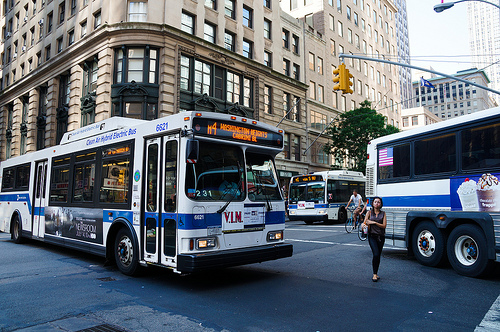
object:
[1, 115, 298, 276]
bus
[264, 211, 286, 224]
blue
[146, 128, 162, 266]
doors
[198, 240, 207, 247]
headlights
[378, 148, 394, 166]
flag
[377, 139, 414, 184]
window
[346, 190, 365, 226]
man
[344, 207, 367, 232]
bicycle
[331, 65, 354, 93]
stoplight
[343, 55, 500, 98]
pole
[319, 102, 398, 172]
tree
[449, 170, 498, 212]
advertisement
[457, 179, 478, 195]
icecream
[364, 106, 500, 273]
bus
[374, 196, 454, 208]
blue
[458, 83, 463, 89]
window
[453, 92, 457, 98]
window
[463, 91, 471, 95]
window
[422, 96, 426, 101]
window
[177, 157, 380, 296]
intersection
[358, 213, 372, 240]
bike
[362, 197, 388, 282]
lady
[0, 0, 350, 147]
buildings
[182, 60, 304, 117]
row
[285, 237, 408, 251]
lines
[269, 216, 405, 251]
crosswalk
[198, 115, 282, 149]
sign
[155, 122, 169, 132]
6621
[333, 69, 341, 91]
light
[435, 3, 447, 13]
light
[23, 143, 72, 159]
edge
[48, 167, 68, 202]
window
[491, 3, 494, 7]
metal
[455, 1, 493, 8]
pole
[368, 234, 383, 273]
jeans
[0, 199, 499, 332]
road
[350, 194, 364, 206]
shirt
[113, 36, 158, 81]
window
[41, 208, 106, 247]
advertisement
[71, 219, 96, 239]
show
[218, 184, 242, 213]
wiper